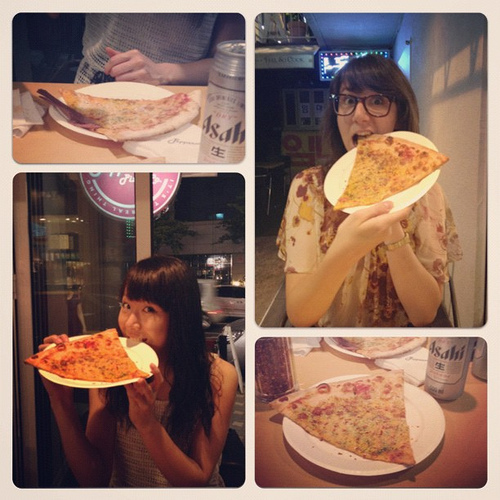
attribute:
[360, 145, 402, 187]
pizza — large, huge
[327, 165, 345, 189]
plate — paper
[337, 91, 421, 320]
woman — biting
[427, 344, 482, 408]
can — beer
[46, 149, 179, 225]
sign — large, red, background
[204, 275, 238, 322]
car — driving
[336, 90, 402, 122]
glasses — brown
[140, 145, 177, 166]
napkins — white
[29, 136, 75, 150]
table — brown, background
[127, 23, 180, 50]
tank top — white